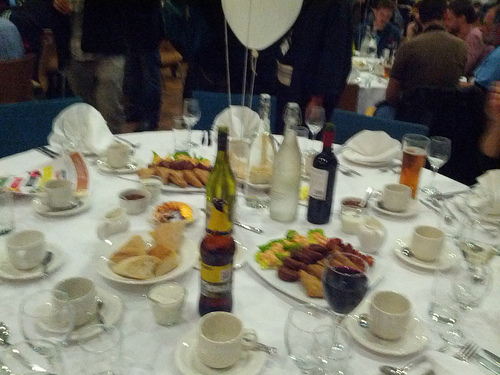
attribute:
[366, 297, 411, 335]
cup — white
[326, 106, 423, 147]
chair — blue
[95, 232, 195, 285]
dish — white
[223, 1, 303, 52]
balloon — white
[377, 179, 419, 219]
cup and saucer — white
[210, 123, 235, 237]
bottle — green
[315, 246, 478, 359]
dishes — silver, white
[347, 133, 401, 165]
napkin — white